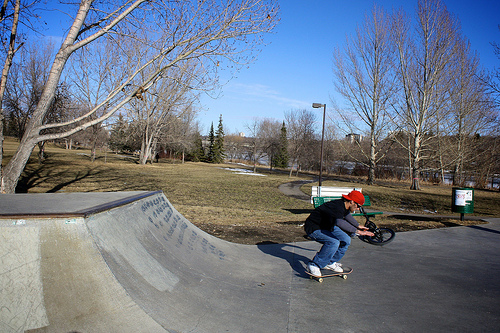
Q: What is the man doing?
A: Skateboarding.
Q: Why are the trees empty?
A: Autumn.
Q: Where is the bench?
A: Behind the man.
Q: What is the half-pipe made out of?
A: Concrete.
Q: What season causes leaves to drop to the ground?
A: Fall.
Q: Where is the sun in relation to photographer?
A: Behind.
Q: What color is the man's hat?
A: Red.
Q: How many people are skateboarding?
A: One.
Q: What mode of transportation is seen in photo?
A: Skateboard.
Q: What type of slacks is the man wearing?
A: Jeans.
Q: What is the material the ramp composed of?
A: Concrete.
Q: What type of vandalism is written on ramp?
A: Graffiti.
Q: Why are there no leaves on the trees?
A: Winter season.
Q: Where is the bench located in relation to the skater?
A: Left side of skater.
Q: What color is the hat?
A: Red.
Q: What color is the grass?
A: Green.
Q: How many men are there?
A: One.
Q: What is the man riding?
A: A skateboard.